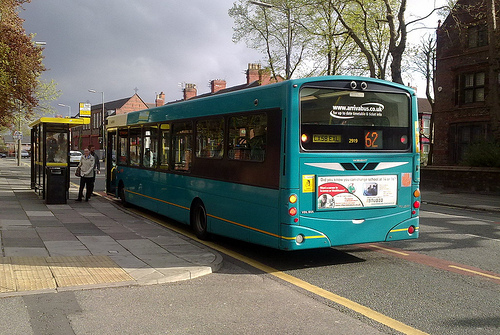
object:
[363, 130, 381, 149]
62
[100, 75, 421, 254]
bus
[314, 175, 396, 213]
ad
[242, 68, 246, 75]
spikes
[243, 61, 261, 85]
chimney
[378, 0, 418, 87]
tree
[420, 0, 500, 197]
building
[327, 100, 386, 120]
website address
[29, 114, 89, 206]
bus stop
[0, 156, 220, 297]
sidewalk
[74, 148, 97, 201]
man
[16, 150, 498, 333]
street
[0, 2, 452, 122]
sky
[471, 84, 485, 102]
window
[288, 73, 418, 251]
rear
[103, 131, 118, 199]
door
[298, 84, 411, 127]
rear windshield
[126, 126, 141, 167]
passenger window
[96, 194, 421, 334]
stripe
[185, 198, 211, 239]
tire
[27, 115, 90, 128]
overhang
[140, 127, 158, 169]
window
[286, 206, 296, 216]
tail light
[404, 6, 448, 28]
branch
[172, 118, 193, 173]
window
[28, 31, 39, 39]
leaves